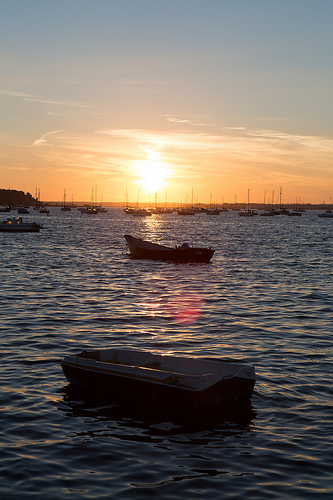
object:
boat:
[60, 348, 257, 411]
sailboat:
[61, 188, 72, 211]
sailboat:
[77, 186, 99, 214]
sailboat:
[176, 192, 194, 215]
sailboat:
[236, 189, 258, 217]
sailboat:
[259, 189, 275, 216]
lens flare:
[160, 291, 204, 325]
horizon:
[39, 200, 332, 206]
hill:
[0, 188, 44, 205]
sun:
[133, 151, 175, 195]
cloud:
[93, 129, 332, 170]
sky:
[0, 0, 332, 205]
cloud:
[165, 116, 205, 126]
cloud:
[219, 125, 246, 134]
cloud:
[30, 129, 63, 147]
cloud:
[23, 97, 93, 108]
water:
[0, 205, 333, 499]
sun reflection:
[141, 208, 164, 232]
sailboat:
[132, 187, 152, 216]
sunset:
[0, 127, 332, 206]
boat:
[124, 234, 216, 263]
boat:
[0, 216, 44, 232]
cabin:
[4, 216, 23, 224]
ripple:
[132, 473, 229, 492]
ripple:
[4, 451, 81, 474]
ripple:
[8, 423, 52, 435]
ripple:
[264, 441, 311, 451]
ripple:
[287, 415, 315, 424]